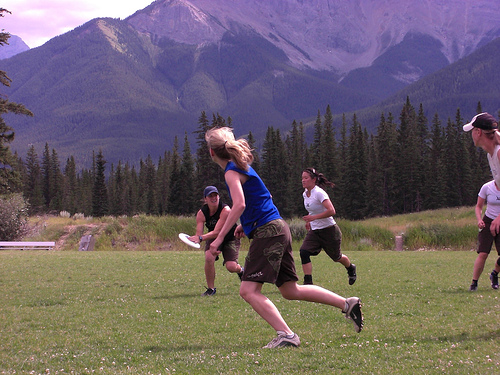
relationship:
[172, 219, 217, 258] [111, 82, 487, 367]
frisbee in park